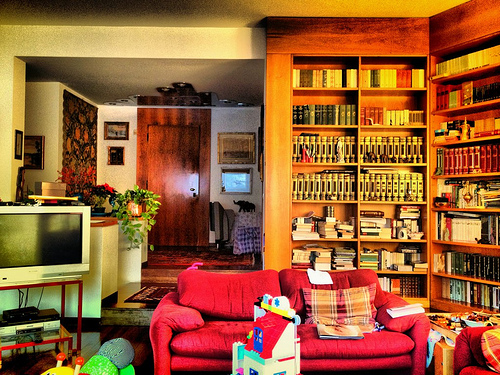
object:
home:
[0, 2, 500, 375]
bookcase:
[253, 14, 431, 308]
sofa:
[146, 269, 226, 374]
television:
[0, 204, 92, 286]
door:
[135, 107, 210, 248]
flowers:
[91, 169, 96, 174]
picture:
[103, 121, 130, 142]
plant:
[110, 184, 162, 251]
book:
[292, 105, 298, 125]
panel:
[171, 82, 194, 93]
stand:
[0, 279, 84, 365]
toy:
[231, 293, 301, 374]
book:
[300, 69, 305, 87]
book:
[385, 302, 426, 318]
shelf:
[293, 88, 357, 91]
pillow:
[301, 282, 379, 326]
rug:
[124, 282, 177, 301]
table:
[0, 323, 75, 366]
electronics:
[4, 295, 44, 311]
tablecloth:
[229, 212, 262, 256]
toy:
[42, 323, 139, 361]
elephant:
[232, 199, 256, 212]